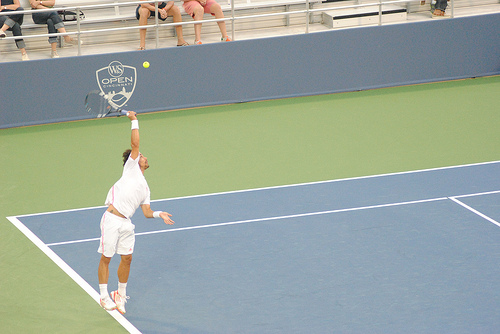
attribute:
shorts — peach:
[184, 1, 234, 33]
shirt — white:
[101, 146, 153, 221]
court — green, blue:
[1, 64, 496, 332]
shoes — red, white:
[91, 289, 236, 301]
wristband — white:
[119, 101, 159, 145]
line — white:
[271, 177, 367, 185]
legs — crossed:
[36, 6, 67, 35]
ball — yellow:
[142, 60, 149, 67]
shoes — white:
[99, 279, 134, 316]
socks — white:
[100, 283, 127, 300]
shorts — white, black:
[96, 212, 137, 258]